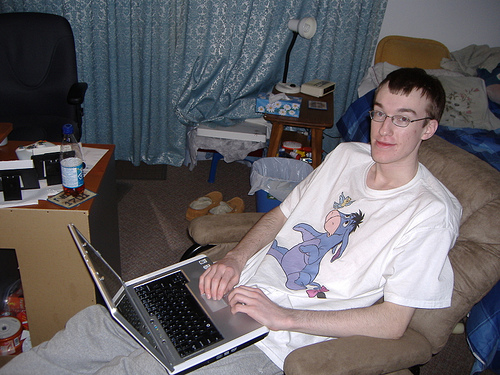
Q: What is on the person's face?
A: Glasses.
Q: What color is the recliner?
A: Brown.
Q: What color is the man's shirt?
A: White.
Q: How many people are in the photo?
A: One.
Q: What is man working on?
A: Laptop.